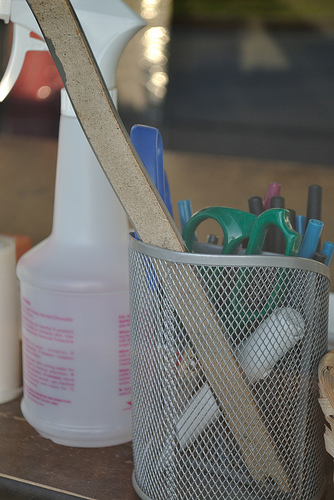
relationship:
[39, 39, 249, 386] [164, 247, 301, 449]
ruler in container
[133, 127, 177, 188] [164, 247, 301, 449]
scissors in container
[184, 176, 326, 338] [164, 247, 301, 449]
pens in container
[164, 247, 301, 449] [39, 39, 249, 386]
container with ruler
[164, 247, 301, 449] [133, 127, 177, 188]
container with scissors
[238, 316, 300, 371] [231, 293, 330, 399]
stick of chalk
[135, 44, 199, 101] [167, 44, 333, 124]
gold in background